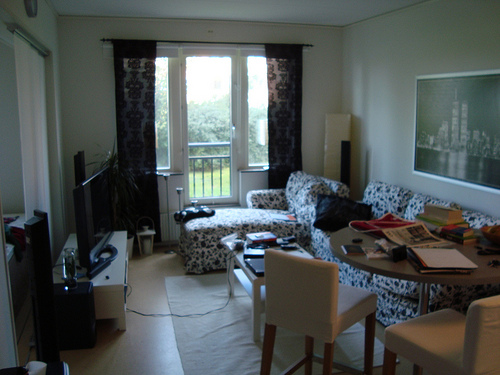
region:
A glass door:
[177, 49, 239, 206]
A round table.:
[327, 199, 498, 286]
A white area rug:
[162, 265, 401, 372]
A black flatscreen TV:
[65, 158, 122, 269]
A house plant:
[90, 142, 146, 242]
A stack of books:
[418, 197, 478, 243]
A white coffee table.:
[217, 220, 328, 341]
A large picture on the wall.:
[403, 61, 498, 199]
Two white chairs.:
[238, 232, 496, 372]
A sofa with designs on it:
[307, 172, 497, 320]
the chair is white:
[257, 244, 368, 341]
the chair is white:
[399, 300, 499, 369]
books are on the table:
[368, 205, 480, 266]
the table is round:
[332, 223, 499, 286]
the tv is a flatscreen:
[78, 166, 120, 266]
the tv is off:
[81, 166, 133, 272]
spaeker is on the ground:
[63, 274, 112, 339]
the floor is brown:
[140, 320, 151, 357]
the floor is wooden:
[136, 307, 169, 365]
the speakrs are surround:
[21, 213, 68, 354]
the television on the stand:
[63, 150, 126, 282]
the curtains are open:
[102, 34, 164, 239]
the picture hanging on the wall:
[413, 64, 497, 200]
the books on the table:
[402, 196, 478, 247]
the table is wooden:
[330, 215, 497, 280]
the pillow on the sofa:
[305, 198, 372, 228]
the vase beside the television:
[54, 241, 84, 293]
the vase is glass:
[60, 243, 85, 293]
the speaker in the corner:
[330, 140, 375, 197]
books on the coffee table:
[242, 224, 278, 243]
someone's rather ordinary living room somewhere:
[2, 0, 499, 374]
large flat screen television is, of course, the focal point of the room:
[73, 154, 123, 269]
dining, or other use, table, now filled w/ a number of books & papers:
[235, 200, 499, 373]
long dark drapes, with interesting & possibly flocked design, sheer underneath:
[109, 35, 309, 260]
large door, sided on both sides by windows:
[157, 42, 264, 257]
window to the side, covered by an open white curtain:
[0, 19, 67, 296]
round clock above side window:
[17, 0, 44, 21]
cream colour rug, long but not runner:
[158, 264, 406, 373]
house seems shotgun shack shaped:
[0, 0, 496, 374]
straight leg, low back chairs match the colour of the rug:
[243, 207, 499, 373]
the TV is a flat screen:
[73, 166, 118, 278]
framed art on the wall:
[410, 69, 497, 195]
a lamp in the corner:
[322, 113, 350, 183]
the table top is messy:
[330, 202, 495, 278]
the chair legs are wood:
[251, 319, 376, 371]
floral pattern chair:
[177, 173, 345, 270]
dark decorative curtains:
[111, 37, 159, 247]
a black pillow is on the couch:
[312, 191, 374, 237]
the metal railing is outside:
[189, 141, 229, 194]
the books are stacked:
[415, 205, 475, 250]